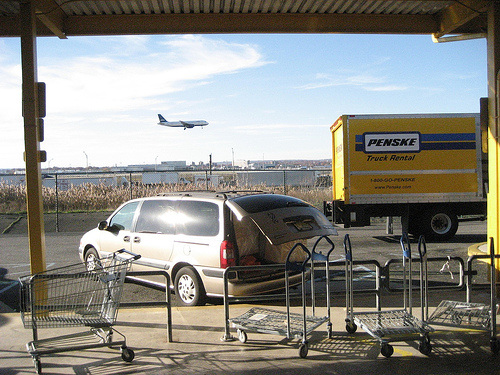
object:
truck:
[320, 99, 497, 244]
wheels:
[413, 205, 460, 243]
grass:
[0, 181, 332, 216]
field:
[0, 211, 114, 234]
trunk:
[224, 192, 330, 282]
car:
[75, 188, 340, 307]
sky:
[0, 34, 485, 175]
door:
[101, 199, 141, 276]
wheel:
[119, 346, 137, 364]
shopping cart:
[17, 247, 143, 375]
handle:
[114, 247, 145, 261]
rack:
[23, 326, 127, 354]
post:
[18, 0, 52, 321]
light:
[218, 238, 236, 268]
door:
[224, 192, 340, 246]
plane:
[154, 113, 212, 131]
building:
[160, 159, 191, 170]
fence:
[0, 168, 333, 232]